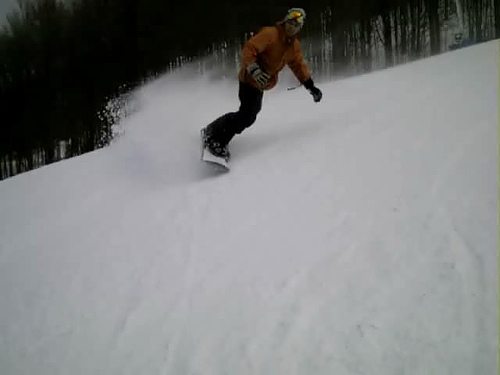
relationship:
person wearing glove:
[201, 3, 325, 160] [302, 72, 327, 106]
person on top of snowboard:
[201, 3, 325, 160] [198, 125, 235, 174]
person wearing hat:
[201, 3, 325, 160] [282, 4, 309, 26]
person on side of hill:
[201, 3, 325, 160] [2, 30, 499, 375]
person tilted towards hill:
[201, 3, 325, 160] [2, 30, 499, 375]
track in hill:
[433, 209, 490, 374] [2, 30, 499, 375]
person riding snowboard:
[201, 3, 325, 160] [198, 125, 235, 174]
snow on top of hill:
[105, 53, 337, 176] [2, 30, 499, 375]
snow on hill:
[105, 53, 337, 176] [2, 30, 499, 375]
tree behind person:
[375, 1, 396, 71] [201, 3, 325, 160]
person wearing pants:
[201, 3, 325, 160] [206, 78, 264, 144]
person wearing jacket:
[201, 3, 325, 160] [237, 25, 312, 88]